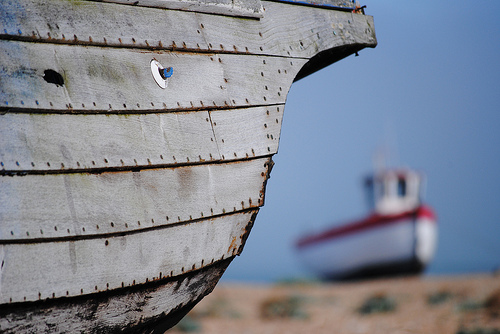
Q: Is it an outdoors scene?
A: Yes, it is outdoors.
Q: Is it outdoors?
A: Yes, it is outdoors.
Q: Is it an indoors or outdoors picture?
A: It is outdoors.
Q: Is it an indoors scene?
A: No, it is outdoors.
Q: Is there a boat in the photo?
A: Yes, there is a boat.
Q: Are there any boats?
A: Yes, there is a boat.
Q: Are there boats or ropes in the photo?
A: Yes, there is a boat.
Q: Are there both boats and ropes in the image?
A: No, there is a boat but no ropes.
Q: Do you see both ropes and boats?
A: No, there is a boat but no ropes.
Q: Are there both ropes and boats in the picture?
A: No, there is a boat but no ropes.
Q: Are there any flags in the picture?
A: No, there are no flags.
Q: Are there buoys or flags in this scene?
A: No, there are no flags or buoys.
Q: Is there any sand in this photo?
A: Yes, there is sand.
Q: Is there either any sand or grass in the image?
A: Yes, there is sand.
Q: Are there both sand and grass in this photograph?
A: No, there is sand but no grass.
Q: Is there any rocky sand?
A: Yes, there is rocky sand.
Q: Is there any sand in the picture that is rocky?
A: Yes, there is sand that is rocky.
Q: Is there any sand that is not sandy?
A: Yes, there is rocky sand.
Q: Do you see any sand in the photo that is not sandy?
A: Yes, there is rocky sand.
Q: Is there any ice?
A: No, there is no ice.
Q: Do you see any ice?
A: No, there is no ice.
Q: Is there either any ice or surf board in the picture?
A: No, there are no ice or surfboards.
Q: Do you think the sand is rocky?
A: Yes, the sand is rocky.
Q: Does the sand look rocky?
A: Yes, the sand is rocky.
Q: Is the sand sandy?
A: No, the sand is rocky.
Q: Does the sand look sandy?
A: No, the sand is rocky.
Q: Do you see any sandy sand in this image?
A: No, there is sand but it is rocky.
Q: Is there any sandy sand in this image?
A: No, there is sand but it is rocky.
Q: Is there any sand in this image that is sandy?
A: No, there is sand but it is rocky.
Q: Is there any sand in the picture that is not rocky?
A: No, there is sand but it is rocky.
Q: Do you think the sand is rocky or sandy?
A: The sand is rocky.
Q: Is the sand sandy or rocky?
A: The sand is rocky.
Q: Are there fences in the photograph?
A: No, there are no fences.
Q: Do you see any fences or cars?
A: No, there are no fences or cars.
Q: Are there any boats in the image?
A: Yes, there is a boat.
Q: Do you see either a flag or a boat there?
A: Yes, there is a boat.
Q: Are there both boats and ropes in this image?
A: No, there is a boat but no ropes.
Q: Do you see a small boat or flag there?
A: Yes, there is a small boat.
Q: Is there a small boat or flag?
A: Yes, there is a small boat.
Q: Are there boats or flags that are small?
A: Yes, the boat is small.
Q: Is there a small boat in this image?
A: Yes, there is a small boat.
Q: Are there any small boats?
A: Yes, there is a small boat.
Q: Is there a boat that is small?
A: Yes, there is a boat that is small.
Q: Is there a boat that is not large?
A: Yes, there is a small boat.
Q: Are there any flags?
A: No, there are no flags.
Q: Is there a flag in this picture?
A: No, there are no flags.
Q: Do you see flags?
A: No, there are no flags.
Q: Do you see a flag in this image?
A: No, there are no flags.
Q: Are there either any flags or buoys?
A: No, there are no flags or buoys.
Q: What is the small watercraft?
A: The watercraft is a boat.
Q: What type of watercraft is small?
A: The watercraft is a boat.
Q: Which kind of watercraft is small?
A: The watercraft is a boat.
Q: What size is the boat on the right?
A: The boat is small.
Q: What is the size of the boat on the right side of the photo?
A: The boat is small.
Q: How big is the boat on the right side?
A: The boat is small.